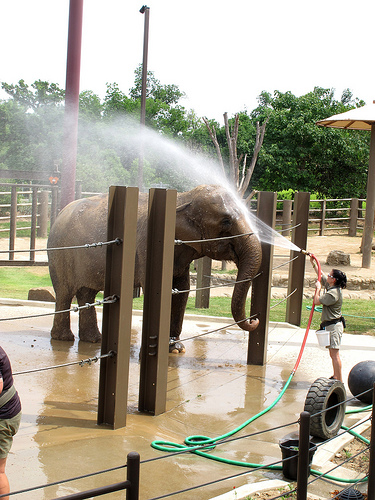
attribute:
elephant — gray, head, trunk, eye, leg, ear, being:
[37, 147, 312, 399]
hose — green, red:
[216, 373, 289, 450]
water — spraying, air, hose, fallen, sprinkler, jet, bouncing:
[67, 115, 301, 294]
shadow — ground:
[39, 384, 135, 449]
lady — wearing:
[298, 258, 346, 375]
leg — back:
[326, 344, 352, 376]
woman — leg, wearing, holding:
[304, 253, 360, 359]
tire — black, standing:
[306, 371, 342, 450]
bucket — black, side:
[264, 428, 333, 497]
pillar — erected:
[103, 196, 191, 449]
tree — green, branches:
[273, 103, 336, 184]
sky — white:
[195, 4, 291, 92]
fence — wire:
[271, 200, 326, 250]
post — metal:
[137, 200, 206, 334]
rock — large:
[284, 229, 357, 294]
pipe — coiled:
[170, 395, 290, 494]